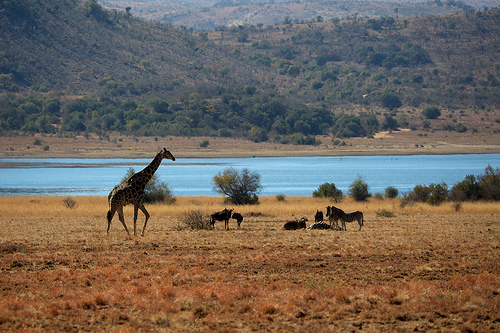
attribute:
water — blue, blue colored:
[0, 157, 492, 194]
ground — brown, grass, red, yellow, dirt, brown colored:
[0, 192, 497, 331]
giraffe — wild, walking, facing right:
[103, 144, 176, 239]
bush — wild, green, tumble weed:
[315, 177, 350, 200]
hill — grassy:
[4, 3, 499, 134]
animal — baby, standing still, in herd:
[230, 211, 247, 231]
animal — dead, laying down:
[312, 216, 346, 235]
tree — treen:
[245, 103, 277, 140]